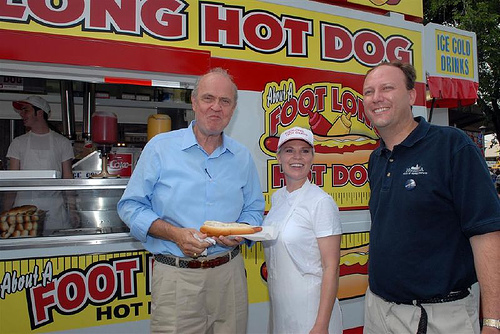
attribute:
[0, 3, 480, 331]
truck — brightly-colored, hot dog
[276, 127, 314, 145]
cap — white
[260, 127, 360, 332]
employee — female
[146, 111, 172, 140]
container — mustard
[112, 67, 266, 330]
man — leather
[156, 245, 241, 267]
belt — brown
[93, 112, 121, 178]
container — large, ketchup, mustard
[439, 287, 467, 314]
belt — black, leather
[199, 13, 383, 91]
words — painted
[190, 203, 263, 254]
hotdog — foot-long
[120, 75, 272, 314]
man — blue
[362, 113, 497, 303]
shirt — blue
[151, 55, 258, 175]
man — short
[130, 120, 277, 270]
shirt — blue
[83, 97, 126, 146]
container — ketchup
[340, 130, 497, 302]
sleeve — short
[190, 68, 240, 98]
hair — blonde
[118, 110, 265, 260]
shirt — long-sleeved, dress